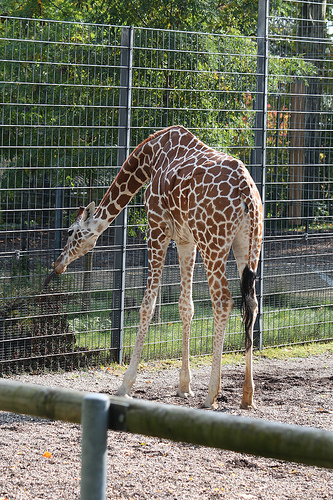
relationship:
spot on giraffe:
[238, 179, 248, 188] [43, 116, 268, 410]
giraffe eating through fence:
[43, 116, 268, 410] [95, 23, 248, 93]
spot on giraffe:
[120, 152, 140, 175] [43, 116, 268, 410]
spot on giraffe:
[75, 239, 83, 244] [43, 116, 268, 410]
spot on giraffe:
[81, 230, 88, 238] [43, 116, 268, 410]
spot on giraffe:
[107, 214, 115, 224] [43, 116, 268, 410]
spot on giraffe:
[101, 208, 108, 220] [43, 116, 268, 410]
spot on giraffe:
[103, 202, 120, 216] [43, 116, 268, 410]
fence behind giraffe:
[0, 2, 319, 377] [43, 116, 268, 410]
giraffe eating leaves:
[43, 116, 268, 410] [48, 93, 93, 114]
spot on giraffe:
[169, 176, 177, 187] [43, 116, 268, 410]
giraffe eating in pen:
[43, 116, 268, 410] [0, 1, 332, 377]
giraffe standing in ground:
[43, 116, 268, 410] [0, 331, 329, 494]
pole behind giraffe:
[4, 374, 332, 468] [43, 116, 268, 410]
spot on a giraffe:
[209, 207, 230, 222] [43, 116, 268, 410]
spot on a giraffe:
[210, 193, 234, 213] [41, 99, 302, 451]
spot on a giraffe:
[147, 192, 162, 216] [43, 116, 268, 410]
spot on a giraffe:
[161, 143, 182, 164] [43, 116, 268, 410]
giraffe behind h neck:
[43, 116, 268, 410] [96, 130, 154, 225]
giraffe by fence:
[21, 118, 281, 416] [0, 2, 319, 377]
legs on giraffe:
[114, 227, 169, 395] [43, 116, 268, 410]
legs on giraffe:
[176, 240, 195, 398] [43, 116, 268, 410]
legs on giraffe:
[199, 248, 235, 410] [43, 116, 268, 410]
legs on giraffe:
[233, 240, 260, 409] [43, 116, 268, 410]